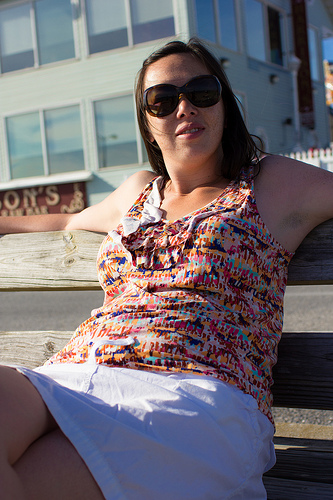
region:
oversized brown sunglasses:
[120, 63, 257, 120]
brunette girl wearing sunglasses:
[83, 22, 275, 179]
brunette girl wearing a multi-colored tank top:
[60, 32, 309, 349]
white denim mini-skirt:
[3, 343, 289, 492]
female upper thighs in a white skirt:
[0, 363, 99, 498]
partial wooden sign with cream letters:
[0, 190, 96, 216]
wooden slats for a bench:
[4, 232, 72, 339]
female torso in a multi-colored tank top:
[123, 174, 280, 376]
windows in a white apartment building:
[8, 12, 120, 170]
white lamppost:
[275, 42, 316, 146]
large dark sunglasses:
[117, 38, 248, 175]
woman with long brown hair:
[116, 42, 276, 199]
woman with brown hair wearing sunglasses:
[82, 35, 284, 206]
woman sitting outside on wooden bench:
[20, 21, 317, 425]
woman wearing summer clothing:
[17, 17, 317, 406]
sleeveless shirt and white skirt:
[26, 158, 302, 487]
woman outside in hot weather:
[13, 21, 306, 422]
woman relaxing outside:
[13, 35, 316, 454]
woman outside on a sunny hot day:
[17, 17, 313, 414]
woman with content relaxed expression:
[102, 31, 281, 189]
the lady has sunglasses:
[129, 68, 227, 116]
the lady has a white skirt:
[18, 353, 278, 499]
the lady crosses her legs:
[0, 364, 110, 495]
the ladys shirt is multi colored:
[54, 181, 276, 386]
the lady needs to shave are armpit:
[273, 205, 311, 240]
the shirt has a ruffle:
[115, 208, 194, 268]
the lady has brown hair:
[122, 34, 267, 185]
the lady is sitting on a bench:
[0, 222, 329, 496]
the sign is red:
[1, 172, 87, 219]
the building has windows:
[0, 2, 123, 176]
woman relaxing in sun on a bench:
[3, 33, 328, 498]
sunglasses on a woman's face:
[130, 76, 237, 118]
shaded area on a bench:
[282, 266, 332, 498]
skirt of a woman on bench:
[20, 341, 292, 498]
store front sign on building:
[0, 178, 100, 224]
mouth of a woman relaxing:
[171, 119, 212, 142]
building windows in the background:
[10, 3, 288, 51]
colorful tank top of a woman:
[52, 168, 297, 406]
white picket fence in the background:
[284, 144, 331, 169]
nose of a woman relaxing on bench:
[175, 105, 200, 121]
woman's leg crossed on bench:
[7, 403, 79, 499]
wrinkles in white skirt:
[87, 398, 223, 459]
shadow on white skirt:
[54, 374, 233, 488]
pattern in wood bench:
[36, 221, 88, 275]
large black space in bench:
[286, 340, 331, 402]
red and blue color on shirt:
[124, 306, 192, 334]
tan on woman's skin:
[155, 194, 232, 224]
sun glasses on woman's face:
[102, 70, 233, 114]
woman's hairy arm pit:
[251, 195, 330, 250]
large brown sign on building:
[16, 174, 110, 237]